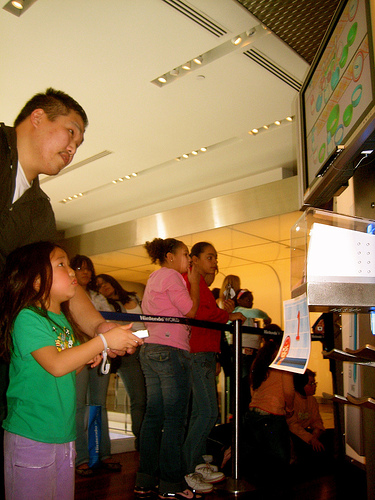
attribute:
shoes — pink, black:
[132, 483, 203, 499]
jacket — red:
[180, 264, 231, 354]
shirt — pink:
[136, 261, 201, 332]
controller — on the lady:
[103, 331, 178, 365]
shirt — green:
[1, 305, 84, 444]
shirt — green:
[7, 298, 95, 456]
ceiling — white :
[69, 29, 125, 76]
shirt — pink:
[137, 262, 194, 354]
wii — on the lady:
[96, 325, 150, 372]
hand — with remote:
[100, 321, 143, 352]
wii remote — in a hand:
[126, 327, 151, 342]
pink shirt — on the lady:
[132, 269, 204, 351]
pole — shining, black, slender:
[225, 318, 246, 479]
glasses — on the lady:
[306, 378, 319, 387]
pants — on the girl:
[7, 444, 71, 493]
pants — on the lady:
[2, 428, 82, 499]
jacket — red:
[186, 270, 227, 351]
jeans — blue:
[131, 339, 227, 491]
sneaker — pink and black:
[161, 488, 199, 498]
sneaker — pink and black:
[131, 481, 159, 497]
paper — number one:
[266, 291, 315, 378]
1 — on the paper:
[292, 309, 303, 345]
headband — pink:
[235, 289, 244, 301]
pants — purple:
[0, 427, 76, 498]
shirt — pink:
[143, 259, 194, 349]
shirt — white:
[79, 282, 115, 322]